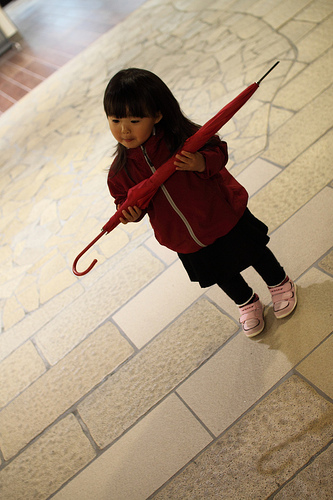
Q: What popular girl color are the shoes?
A: Pink.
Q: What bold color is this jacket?
A: Red.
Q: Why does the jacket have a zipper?
A: To zip up.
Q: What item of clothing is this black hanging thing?
A: Skirt.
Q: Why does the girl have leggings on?
A: To keep warm.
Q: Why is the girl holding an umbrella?
A: Rain.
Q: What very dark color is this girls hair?
A: Black.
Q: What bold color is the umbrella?
A: Red.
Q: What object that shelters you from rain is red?
A: Umbrella.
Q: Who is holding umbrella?
A: Little girl.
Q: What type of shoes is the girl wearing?
A: Pink velcro sneakers.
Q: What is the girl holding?
A: Red umbrella.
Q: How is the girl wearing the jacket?
A: Zipped up.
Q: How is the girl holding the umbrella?
A: With both hands.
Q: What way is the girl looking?
A: To left.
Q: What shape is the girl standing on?
A: Rectangle.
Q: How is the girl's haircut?
A: With bangs.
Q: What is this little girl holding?
A: A red umbrella.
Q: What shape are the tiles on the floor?
A: Rectangle.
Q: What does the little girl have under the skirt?
A: Black tights.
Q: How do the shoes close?
A: With Velcro.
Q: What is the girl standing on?
A: A tile floor.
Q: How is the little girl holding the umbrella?
A: With her hands.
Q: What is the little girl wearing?
A: A red jacket.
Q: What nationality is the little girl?
A: Asian.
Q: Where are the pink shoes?
A: On the girl's feet.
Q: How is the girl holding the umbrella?
A: Horizontally.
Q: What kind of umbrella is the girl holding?
A: Red.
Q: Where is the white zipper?
A: On the girl's jacket.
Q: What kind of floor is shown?
A: Tile.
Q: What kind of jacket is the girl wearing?
A: Red.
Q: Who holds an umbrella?
A: The little girl.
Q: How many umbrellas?
A: One.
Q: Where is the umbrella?
A: In the little girl's hand.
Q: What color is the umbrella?
A: Red.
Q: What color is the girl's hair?
A: Black.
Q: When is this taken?
A: During the rain.